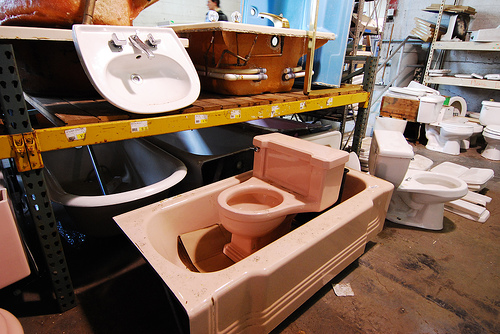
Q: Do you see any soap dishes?
A: No, there are no soap dishes.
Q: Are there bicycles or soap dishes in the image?
A: No, there are no soap dishes or bicycles.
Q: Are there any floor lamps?
A: No, there are no floor lamps.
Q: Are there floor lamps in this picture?
A: No, there are no floor lamps.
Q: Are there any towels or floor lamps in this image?
A: No, there are no floor lamps or towels.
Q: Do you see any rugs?
A: No, there are no rugs.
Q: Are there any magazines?
A: No, there are no magazines.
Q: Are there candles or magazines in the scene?
A: No, there are no magazines or candles.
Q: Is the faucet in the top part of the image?
A: Yes, the faucet is in the top of the image.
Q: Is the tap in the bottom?
A: No, the tap is in the top of the image.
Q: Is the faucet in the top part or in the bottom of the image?
A: The faucet is in the top of the image.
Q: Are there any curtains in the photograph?
A: No, there are no curtains.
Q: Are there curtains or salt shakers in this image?
A: No, there are no curtains or salt shakers.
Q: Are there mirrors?
A: No, there are no mirrors.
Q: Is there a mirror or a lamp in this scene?
A: No, there are no mirrors or lamps.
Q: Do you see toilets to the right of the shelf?
A: Yes, there is a toilet to the right of the shelf.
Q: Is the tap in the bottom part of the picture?
A: No, the tap is in the top of the image.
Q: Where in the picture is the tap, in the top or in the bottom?
A: The tap is in the top of the image.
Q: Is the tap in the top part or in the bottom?
A: The tap is in the top of the image.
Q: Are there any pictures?
A: No, there are no pictures.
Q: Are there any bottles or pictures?
A: No, there are no pictures or bottles.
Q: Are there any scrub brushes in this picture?
A: No, there are no scrub brushes.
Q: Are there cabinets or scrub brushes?
A: No, there are no scrub brushes or cabinets.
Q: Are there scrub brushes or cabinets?
A: No, there are no scrub brushes or cabinets.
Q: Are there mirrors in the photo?
A: No, there are no mirrors.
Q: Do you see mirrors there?
A: No, there are no mirrors.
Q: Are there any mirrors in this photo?
A: No, there are no mirrors.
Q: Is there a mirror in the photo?
A: No, there are no mirrors.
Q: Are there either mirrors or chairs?
A: No, there are no mirrors or chairs.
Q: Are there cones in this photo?
A: No, there are no cones.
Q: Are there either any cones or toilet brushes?
A: No, there are no cones or toilet brushes.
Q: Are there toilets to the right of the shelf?
A: Yes, there is a toilet to the right of the shelf.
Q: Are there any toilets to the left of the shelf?
A: No, the toilet is to the right of the shelf.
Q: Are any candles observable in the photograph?
A: No, there are no candles.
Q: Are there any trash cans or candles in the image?
A: No, there are no candles or trash cans.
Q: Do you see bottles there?
A: No, there are no bottles.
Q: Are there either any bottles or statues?
A: No, there are no bottles or statues.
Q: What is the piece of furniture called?
A: The piece of furniture is a shelf.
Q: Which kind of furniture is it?
A: The piece of furniture is a shelf.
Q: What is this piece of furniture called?
A: This is a shelf.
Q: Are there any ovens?
A: No, there are no ovens.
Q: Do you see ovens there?
A: No, there are no ovens.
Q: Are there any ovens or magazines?
A: No, there are no ovens or magazines.